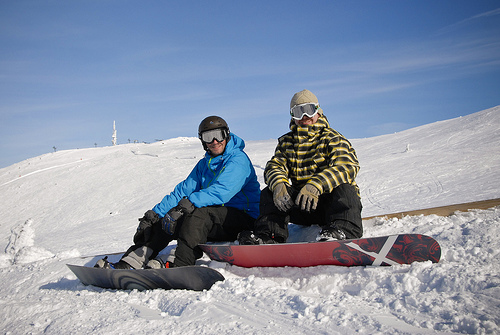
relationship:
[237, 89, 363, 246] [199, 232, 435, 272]
man on a board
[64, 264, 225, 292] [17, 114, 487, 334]
board sitting in snow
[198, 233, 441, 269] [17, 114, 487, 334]
board sitting in snow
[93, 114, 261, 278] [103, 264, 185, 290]
boarder on board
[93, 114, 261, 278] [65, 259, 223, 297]
boarder on snowboard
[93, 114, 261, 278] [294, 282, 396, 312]
boarder sitting in snow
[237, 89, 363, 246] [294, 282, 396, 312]
man sitting in snow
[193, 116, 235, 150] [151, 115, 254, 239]
helmet on man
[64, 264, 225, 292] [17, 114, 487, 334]
board in snow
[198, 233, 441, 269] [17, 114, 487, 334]
board in snow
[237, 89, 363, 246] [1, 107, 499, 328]
man sitting on hill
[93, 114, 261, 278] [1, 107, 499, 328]
boarder sitting on hill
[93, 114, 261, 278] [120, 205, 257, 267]
boarder wearing snow pants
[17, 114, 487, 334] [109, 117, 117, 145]
snow covered tree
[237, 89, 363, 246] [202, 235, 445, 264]
man on snowboard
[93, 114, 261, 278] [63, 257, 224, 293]
boarder on snowboard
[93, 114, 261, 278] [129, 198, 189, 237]
boarder wearing gloves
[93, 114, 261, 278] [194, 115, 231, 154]
boarder wearing a helmet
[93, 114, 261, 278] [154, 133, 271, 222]
boarder wearing a jacket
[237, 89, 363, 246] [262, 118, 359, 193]
man wearing a coat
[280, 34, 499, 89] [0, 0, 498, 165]
white clouds in blue sky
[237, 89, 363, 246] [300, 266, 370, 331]
man sitting on snow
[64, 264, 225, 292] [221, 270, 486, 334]
board in snow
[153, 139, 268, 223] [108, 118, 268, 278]
jacket on boarder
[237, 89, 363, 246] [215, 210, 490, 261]
man on board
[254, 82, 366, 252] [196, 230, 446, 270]
man on snowboard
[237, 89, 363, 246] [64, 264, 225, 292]
man wearing board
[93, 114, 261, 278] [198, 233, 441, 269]
boarder wearing board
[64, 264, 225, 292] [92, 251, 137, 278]
board on foot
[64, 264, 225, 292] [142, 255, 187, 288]
board on foot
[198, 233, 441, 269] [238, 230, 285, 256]
board on foot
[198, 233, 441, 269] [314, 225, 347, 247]
board on foot